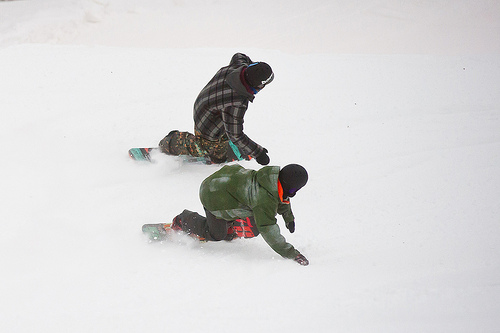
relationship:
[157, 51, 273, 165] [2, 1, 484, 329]
child on snow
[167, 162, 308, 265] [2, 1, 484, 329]
child on snow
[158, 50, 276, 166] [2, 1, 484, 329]
child playing in snow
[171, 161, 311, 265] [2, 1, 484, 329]
child playing in snow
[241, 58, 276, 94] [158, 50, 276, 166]
head belonging to child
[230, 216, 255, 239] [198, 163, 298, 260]
design adorning snowsuit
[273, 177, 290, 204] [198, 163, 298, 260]
collar lining snowsuit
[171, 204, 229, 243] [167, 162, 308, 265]
leg belonging to child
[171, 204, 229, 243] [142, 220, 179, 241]
leg attached to ski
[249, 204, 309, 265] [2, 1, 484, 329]
right arm touching snow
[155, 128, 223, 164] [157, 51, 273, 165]
leg belonging to child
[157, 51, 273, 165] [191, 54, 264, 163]
child wearing snowsuit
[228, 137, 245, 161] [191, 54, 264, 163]
design adorning snowsuit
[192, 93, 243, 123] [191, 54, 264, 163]
stripe adorning snowsuit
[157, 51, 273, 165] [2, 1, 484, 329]
child snowboarding in snow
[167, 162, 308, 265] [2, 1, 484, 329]
child snowboarding in snow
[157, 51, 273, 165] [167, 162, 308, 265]
child snowboarding next to child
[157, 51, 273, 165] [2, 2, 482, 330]
child leaning toward ground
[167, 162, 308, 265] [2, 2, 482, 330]
child leaning toward ground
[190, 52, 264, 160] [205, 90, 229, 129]
coat has stripes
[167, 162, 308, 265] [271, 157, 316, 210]
child wearing cap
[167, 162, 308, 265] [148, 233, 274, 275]
child are on snow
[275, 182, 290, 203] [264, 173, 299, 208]
orange around neck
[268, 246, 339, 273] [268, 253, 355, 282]
hand touches ground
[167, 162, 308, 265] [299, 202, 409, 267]
child snowboarding in snow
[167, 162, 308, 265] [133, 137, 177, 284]
child riding snowboards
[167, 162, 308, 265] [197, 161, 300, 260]
child wearing clothing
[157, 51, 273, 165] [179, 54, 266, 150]
child wearing coat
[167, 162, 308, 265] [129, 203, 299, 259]
child leaning on snowboard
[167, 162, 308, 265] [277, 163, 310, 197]
child in cap